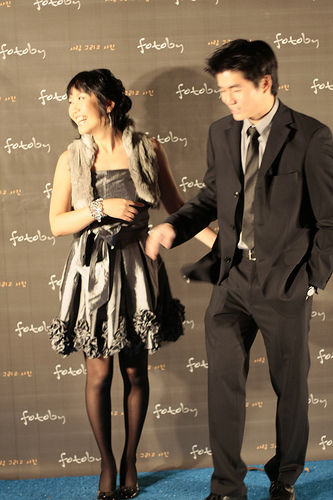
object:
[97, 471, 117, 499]
heels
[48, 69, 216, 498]
people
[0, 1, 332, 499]
backdrop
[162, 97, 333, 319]
suit jacket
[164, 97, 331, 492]
suit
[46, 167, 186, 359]
dress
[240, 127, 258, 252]
tie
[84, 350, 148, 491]
stockings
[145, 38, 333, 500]
he (man)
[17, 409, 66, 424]
text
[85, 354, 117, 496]
hosiery